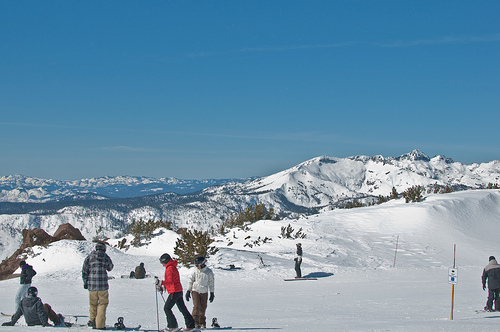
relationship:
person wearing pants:
[187, 257, 217, 329] [188, 290, 209, 330]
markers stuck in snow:
[445, 240, 472, 329] [393, 280, 456, 326]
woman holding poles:
[154, 252, 194, 331] [152, 279, 170, 325]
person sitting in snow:
[15, 287, 66, 327] [53, 290, 80, 311]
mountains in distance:
[0, 170, 292, 199] [10, 169, 131, 193]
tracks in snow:
[366, 243, 418, 261] [369, 232, 450, 307]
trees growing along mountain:
[138, 215, 273, 235] [173, 185, 297, 236]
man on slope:
[80, 243, 116, 331] [21, 248, 273, 308]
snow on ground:
[251, 291, 290, 307] [246, 261, 380, 329]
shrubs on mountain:
[233, 208, 271, 221] [183, 175, 314, 259]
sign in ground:
[448, 264, 459, 283] [402, 295, 474, 329]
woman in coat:
[154, 251, 188, 329] [160, 260, 183, 291]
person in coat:
[187, 257, 217, 325] [184, 267, 218, 297]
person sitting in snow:
[0, 287, 66, 328] [56, 286, 80, 313]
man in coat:
[481, 256, 497, 311] [483, 265, 497, 283]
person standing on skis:
[295, 240, 306, 278] [282, 275, 319, 283]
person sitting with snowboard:
[130, 259, 146, 276] [117, 272, 151, 280]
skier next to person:
[157, 252, 193, 327] [187, 257, 217, 329]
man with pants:
[75, 230, 157, 305] [81, 289, 132, 329]